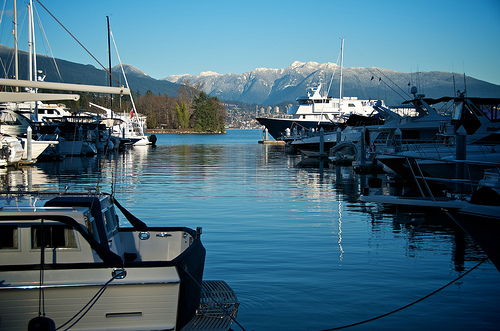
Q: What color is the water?
A: Blue.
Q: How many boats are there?
A: 10.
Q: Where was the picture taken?
A: At the docks.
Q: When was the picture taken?
A: In the day time.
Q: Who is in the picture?
A: No one.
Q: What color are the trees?
A: Green.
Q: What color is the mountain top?
A: White.